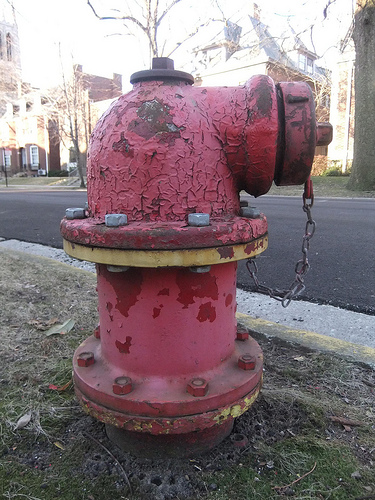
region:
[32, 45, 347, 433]
the fire hydrant is old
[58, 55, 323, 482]
paint on the fire hydrant is chipping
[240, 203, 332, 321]
the chain is gray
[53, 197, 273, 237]
the bolts are gray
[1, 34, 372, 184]
houses behind the fire hydrant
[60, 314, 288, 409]
the bolts are red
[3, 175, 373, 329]
the road is black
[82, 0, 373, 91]
the tree branches are bare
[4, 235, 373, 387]
a yellow line beside the road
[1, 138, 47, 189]
the house has windows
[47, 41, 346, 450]
fire hydrant is red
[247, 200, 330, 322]
a chain attached to a hose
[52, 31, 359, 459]
an hydrant on the ground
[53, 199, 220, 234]
three bolts on a fire hydrant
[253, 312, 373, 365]
a yellow line on the road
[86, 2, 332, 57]
branches seen above the hydrant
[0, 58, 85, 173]
a building in the other side of the road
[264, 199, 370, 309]
road is paved with black pavement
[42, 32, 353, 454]
the paint of the hydrant is decaying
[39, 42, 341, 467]
fire hydrant is old and rusty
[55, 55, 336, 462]
fire hydrant in the ground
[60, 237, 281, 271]
yellow ring around the fire hydrant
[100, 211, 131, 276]
silver screw in the fire hydrant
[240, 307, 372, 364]
yellow line on the street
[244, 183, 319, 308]
chain holding fire hydrant parts together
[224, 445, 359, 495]
grass growing in the dirt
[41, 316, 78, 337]
grey leaf on the dirt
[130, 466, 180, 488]
black holes in the dirt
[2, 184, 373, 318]
black, long street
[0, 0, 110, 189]
builging on the other side of the street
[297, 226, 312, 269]
chain on fire hydrant.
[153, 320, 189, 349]
red paint on hydrant.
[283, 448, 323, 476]
grass on the ground.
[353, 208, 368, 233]
blacktop on the street.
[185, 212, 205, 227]
bolt on the hydrant.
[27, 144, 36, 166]
window on the building.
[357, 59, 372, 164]
trunk of the tree.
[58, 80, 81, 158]
bare tree across the street.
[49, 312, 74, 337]
leaf in the grass.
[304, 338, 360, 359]
yellow paint on curb.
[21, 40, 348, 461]
A fire hydrant is pictured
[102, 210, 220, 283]
Bolts are holding the hydrant together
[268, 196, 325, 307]
This is a chain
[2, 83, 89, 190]
A building is in the background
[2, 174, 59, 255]
A paved street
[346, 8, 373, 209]
A tree trunk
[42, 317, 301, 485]
The hydrant is in the ground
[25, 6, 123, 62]
The sky is bright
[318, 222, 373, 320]
The road is paved with asphalt